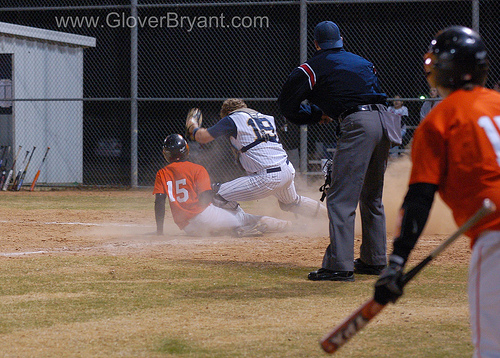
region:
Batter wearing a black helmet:
[408, 22, 498, 107]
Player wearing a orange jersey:
[385, 78, 498, 240]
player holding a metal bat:
[308, 167, 499, 357]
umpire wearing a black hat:
[298, 12, 355, 66]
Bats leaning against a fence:
[7, 131, 60, 201]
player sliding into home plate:
[145, 159, 281, 260]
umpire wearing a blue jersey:
[274, 42, 400, 146]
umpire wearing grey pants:
[322, 102, 404, 292]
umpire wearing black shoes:
[301, 249, 398, 288]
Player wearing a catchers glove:
[178, 104, 214, 145]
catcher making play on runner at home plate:
[120, 90, 327, 267]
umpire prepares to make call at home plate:
[283, 23, 401, 287]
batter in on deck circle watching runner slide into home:
[319, 27, 497, 352]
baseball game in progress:
[0, 2, 497, 354]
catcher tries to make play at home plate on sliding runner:
[150, 92, 320, 233]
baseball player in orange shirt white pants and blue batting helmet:
[312, 25, 495, 352]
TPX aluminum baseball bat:
[316, 198, 493, 354]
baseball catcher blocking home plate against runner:
[148, 95, 325, 237]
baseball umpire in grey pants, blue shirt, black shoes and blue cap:
[277, 20, 402, 280]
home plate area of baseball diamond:
[4, 0, 497, 355]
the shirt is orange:
[152, 163, 224, 218]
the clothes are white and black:
[223, 108, 300, 204]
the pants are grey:
[333, 110, 395, 269]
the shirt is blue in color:
[318, 54, 375, 93]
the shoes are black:
[306, 246, 369, 297]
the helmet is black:
[428, 22, 494, 84]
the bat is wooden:
[310, 205, 497, 354]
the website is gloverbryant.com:
[54, 10, 288, 33]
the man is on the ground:
[140, 97, 265, 257]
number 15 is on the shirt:
[163, 175, 200, 217]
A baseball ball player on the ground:
[142, 138, 242, 260]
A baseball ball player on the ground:
[190, 98, 281, 196]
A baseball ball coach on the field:
[293, 16, 379, 271]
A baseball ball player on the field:
[413, 16, 498, 354]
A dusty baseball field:
[68, 186, 155, 262]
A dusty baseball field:
[193, 209, 318, 291]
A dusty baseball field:
[8, 206, 128, 333]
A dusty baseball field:
[152, 270, 236, 357]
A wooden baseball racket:
[319, 191, 488, 353]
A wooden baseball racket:
[27, 146, 61, 201]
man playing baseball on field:
[118, 128, 250, 290]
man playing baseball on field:
[198, 80, 279, 205]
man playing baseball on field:
[320, 0, 385, 317]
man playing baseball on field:
[410, 29, 497, 264]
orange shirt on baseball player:
[159, 136, 224, 231]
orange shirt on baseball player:
[405, 82, 487, 232]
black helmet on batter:
[402, 12, 498, 100]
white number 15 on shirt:
[145, 162, 246, 227]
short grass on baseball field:
[108, 263, 283, 325]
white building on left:
[7, 23, 108, 203]